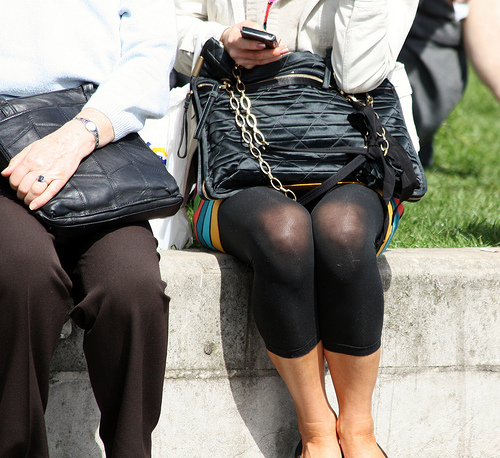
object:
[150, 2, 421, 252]
shirt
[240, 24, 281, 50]
cell phone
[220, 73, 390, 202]
chain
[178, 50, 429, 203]
bag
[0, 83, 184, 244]
purse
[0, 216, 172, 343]
lap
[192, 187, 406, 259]
rainbow skirt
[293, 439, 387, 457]
shoes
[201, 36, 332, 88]
strap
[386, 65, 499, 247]
ground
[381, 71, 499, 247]
grass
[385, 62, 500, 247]
field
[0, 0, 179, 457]
woman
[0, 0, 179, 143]
shirt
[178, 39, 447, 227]
bag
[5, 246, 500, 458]
wall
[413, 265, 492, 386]
wall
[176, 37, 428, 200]
purse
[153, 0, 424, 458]
person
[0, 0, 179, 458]
person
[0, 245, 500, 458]
concrete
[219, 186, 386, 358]
leggings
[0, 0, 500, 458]
people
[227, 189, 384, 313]
lap